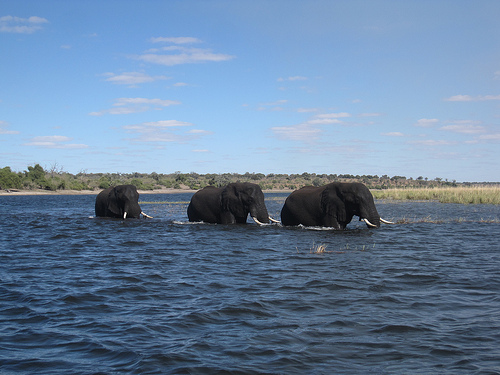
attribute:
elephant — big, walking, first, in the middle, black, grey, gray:
[281, 183, 391, 229]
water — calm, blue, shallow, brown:
[6, 196, 500, 374]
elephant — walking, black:
[187, 182, 270, 225]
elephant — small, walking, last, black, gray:
[95, 185, 140, 219]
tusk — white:
[379, 215, 395, 225]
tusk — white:
[362, 218, 378, 227]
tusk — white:
[269, 214, 280, 223]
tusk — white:
[253, 218, 268, 227]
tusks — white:
[123, 211, 151, 220]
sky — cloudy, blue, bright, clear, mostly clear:
[3, 3, 495, 169]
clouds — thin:
[102, 35, 233, 145]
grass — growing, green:
[297, 243, 343, 252]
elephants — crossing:
[94, 180, 390, 230]